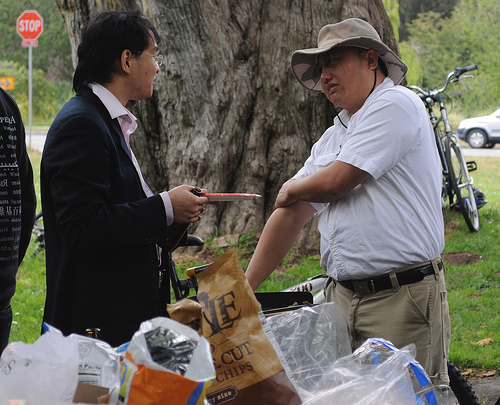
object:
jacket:
[39, 81, 174, 347]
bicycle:
[394, 64, 490, 234]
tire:
[447, 361, 480, 405]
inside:
[146, 326, 196, 376]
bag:
[94, 313, 215, 405]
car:
[457, 107, 500, 150]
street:
[23, 126, 500, 157]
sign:
[16, 10, 44, 48]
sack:
[0, 246, 460, 404]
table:
[0, 247, 457, 405]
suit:
[36, 82, 176, 346]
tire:
[467, 129, 488, 150]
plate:
[201, 192, 263, 198]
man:
[39, 10, 208, 349]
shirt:
[294, 76, 444, 282]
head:
[317, 38, 378, 109]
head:
[70, 10, 162, 102]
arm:
[288, 89, 424, 203]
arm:
[241, 180, 332, 327]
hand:
[156, 184, 209, 224]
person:
[39, 11, 206, 345]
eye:
[326, 56, 341, 66]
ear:
[365, 50, 379, 71]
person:
[244, 17, 449, 394]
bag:
[167, 246, 304, 405]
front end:
[453, 112, 475, 150]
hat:
[289, 18, 407, 93]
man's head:
[315, 33, 387, 107]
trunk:
[54, 0, 430, 258]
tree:
[54, 0, 408, 259]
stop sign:
[16, 10, 44, 48]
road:
[24, 126, 48, 154]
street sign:
[0, 76, 14, 91]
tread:
[448, 360, 463, 378]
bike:
[445, 361, 478, 404]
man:
[244, 17, 448, 392]